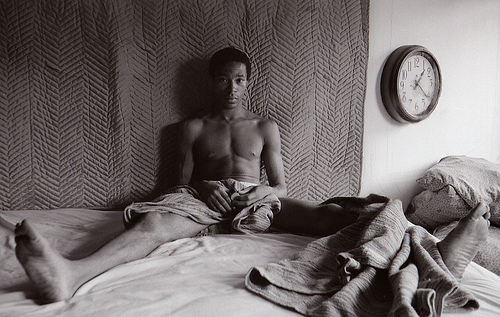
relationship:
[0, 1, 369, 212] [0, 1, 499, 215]
fabric hanging on wall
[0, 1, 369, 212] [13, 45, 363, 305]
fabric behind boy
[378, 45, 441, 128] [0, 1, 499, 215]
clock hanging on wall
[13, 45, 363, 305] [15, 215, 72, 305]
boy has right foot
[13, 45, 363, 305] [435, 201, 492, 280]
boy has left foot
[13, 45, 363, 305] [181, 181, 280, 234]
boy has a lap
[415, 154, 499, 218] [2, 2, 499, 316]
pillow in room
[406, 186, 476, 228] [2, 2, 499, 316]
pillow in room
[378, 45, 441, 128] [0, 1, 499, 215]
clock on wall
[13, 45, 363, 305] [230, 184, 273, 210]
boy has a hand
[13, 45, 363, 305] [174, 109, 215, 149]
boy has a right shoulder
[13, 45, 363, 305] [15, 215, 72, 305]
boy has a right foot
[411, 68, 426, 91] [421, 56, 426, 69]
hand on 1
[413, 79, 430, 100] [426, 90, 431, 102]
hand on 4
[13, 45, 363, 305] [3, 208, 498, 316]
boy sitting on a bed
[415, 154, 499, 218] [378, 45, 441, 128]
pillow underneath clock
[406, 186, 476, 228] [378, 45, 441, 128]
pillow underneath clock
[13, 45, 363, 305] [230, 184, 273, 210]
boy has hand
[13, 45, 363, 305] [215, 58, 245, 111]
boy has a face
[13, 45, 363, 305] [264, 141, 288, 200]
boy has an arm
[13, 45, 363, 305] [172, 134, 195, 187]
boy has an arm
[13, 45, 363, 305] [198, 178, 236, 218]
boy has a hand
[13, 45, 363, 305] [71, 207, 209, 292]
boy has a leg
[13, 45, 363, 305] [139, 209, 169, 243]
boy has a knee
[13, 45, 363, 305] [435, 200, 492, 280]
boy has a foot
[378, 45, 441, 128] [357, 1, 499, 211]
clock hanging on wall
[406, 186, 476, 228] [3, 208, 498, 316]
pillow are beside bed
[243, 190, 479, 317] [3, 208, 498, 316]
blanket on bed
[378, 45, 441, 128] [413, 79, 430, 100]
clock has hand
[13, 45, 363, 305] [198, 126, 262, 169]
boy has a chest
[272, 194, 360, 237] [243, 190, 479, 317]
leg underneath blanket